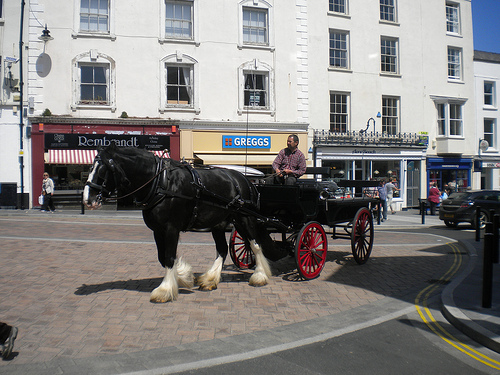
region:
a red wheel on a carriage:
[291, 215, 326, 270]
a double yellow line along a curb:
[410, 275, 495, 355]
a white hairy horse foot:
[200, 250, 225, 291]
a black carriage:
[242, 155, 388, 271]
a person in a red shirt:
[424, 182, 445, 211]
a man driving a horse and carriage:
[270, 123, 310, 196]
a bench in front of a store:
[43, 183, 91, 208]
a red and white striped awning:
[39, 145, 101, 171]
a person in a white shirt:
[37, 169, 63, 213]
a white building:
[302, 0, 479, 204]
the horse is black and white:
[70, 135, 345, 367]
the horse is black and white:
[91, 142, 221, 257]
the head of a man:
[283, 128, 304, 151]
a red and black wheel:
[292, 219, 337, 285]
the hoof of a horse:
[148, 280, 178, 308]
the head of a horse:
[71, 135, 126, 215]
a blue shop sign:
[218, 129, 273, 152]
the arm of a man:
[289, 152, 308, 179]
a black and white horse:
[68, 135, 275, 302]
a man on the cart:
[271, 125, 311, 186]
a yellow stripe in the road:
[409, 227, 499, 373]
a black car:
[434, 182, 499, 232]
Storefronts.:
[25, 115, 467, 212]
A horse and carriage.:
[70, 120, 395, 302]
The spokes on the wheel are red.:
[290, 201, 385, 281]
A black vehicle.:
[431, 180, 496, 230]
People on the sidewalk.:
[375, 175, 441, 220]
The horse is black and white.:
[75, 135, 270, 300]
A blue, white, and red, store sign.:
[210, 126, 275, 151]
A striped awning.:
[37, 142, 94, 163]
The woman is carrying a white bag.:
[25, 160, 60, 215]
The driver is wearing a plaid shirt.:
[257, 121, 317, 211]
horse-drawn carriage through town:
[52, 113, 403, 300]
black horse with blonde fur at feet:
[65, 120, 276, 302]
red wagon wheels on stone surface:
[222, 205, 392, 285]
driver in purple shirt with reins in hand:
[255, 115, 320, 195]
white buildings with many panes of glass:
[55, 11, 495, 123]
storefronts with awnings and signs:
[25, 122, 491, 212]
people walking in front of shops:
[370, 152, 461, 227]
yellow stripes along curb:
[405, 210, 491, 362]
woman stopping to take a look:
[5, 136, 70, 216]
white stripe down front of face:
[65, 138, 130, 215]